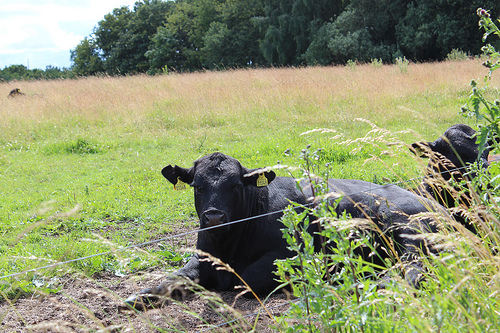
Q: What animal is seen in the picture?
A: Cow.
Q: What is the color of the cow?
A: Black.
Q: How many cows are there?
A: 2.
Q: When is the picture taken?
A: Daytime.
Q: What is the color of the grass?
A: Green.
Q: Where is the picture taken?
A: In a grassland.